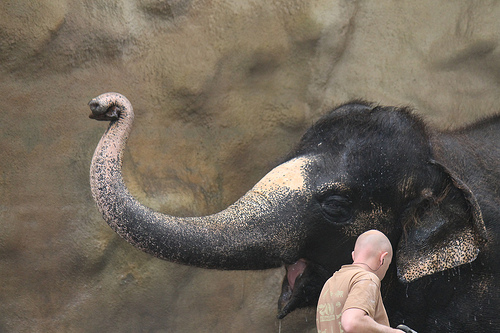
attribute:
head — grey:
[276, 100, 486, 320]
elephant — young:
[37, 70, 487, 265]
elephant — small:
[70, 78, 499, 330]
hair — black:
[354, 109, 415, 187]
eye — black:
[321, 189, 360, 222]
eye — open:
[323, 193, 346, 212]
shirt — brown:
[322, 233, 382, 332]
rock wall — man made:
[2, 2, 488, 329]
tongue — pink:
[276, 248, 319, 303]